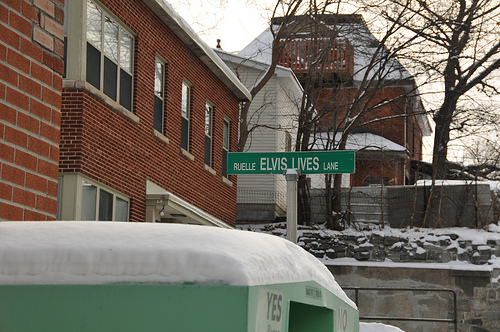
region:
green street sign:
[230, 154, 355, 172]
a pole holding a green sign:
[282, 167, 302, 238]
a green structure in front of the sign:
[7, 283, 356, 329]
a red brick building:
[73, 90, 245, 207]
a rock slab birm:
[257, 225, 496, 282]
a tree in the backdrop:
[429, 12, 499, 152]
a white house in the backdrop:
[242, 70, 297, 209]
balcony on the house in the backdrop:
[271, 34, 356, 66]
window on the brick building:
[87, 7, 133, 109]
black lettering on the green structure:
[263, 290, 284, 320]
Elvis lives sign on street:
[223, 146, 363, 175]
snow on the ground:
[437, 226, 499, 253]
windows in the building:
[83, 1, 153, 136]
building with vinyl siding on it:
[227, 55, 327, 229]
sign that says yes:
[258, 282, 289, 327]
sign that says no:
[331, 302, 360, 330]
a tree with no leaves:
[386, 0, 498, 191]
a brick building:
[70, 5, 238, 230]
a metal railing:
[319, 277, 467, 327]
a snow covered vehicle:
[0, 222, 360, 302]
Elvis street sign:
[211, 148, 376, 184]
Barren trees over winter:
[405, 10, 465, 102]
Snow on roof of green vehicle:
[136, 215, 311, 311]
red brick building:
[80, 105, 161, 181]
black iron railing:
[376, 265, 458, 326]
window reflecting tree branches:
[71, 3, 163, 72]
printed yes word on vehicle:
[231, 276, 320, 323]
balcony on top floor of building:
[268, 9, 370, 83]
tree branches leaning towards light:
[286, 43, 441, 146]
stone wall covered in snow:
[363, 198, 493, 282]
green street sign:
[215, 133, 356, 193]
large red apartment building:
[22, 0, 387, 250]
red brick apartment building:
[60, 50, 347, 236]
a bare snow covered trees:
[305, 7, 495, 157]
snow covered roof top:
[156, 0, 246, 105]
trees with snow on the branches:
[310, 15, 490, 135]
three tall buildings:
[70, 10, 480, 235]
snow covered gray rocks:
[260, 190, 490, 305]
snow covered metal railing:
[310, 255, 470, 325]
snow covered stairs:
[288, 156, 398, 237]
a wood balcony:
[269, 20, 369, 93]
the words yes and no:
[246, 278, 357, 330]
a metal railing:
[334, 275, 474, 328]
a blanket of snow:
[8, 205, 361, 308]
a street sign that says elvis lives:
[213, 137, 360, 188]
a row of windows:
[77, 32, 241, 179]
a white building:
[210, 41, 329, 212]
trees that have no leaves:
[243, 7, 473, 204]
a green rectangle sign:
[218, 147, 360, 175]